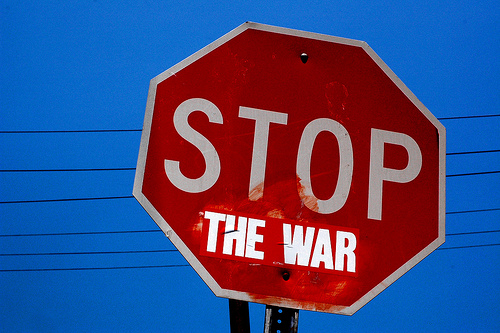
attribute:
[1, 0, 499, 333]
sky — blue, clear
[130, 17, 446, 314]
stop sign — red, white, octagonal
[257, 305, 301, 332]
pole — metal, black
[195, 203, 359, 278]
sticker — red, white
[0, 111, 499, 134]
power line — black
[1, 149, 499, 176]
power line — black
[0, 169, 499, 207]
power line — black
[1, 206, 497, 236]
power line — black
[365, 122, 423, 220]
letter p — white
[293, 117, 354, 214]
letter o — white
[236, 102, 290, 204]
letter t — white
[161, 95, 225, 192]
letter s — white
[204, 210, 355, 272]
letters — white, large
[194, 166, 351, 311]
paint — smeared